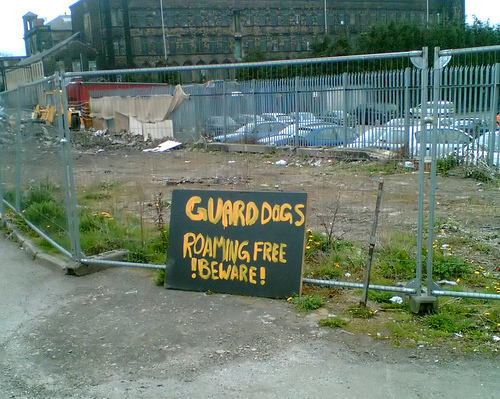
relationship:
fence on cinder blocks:
[2, 44, 500, 301] [409, 292, 439, 315]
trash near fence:
[388, 292, 403, 305] [2, 44, 500, 301]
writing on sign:
[182, 194, 304, 286] [162, 189, 309, 299]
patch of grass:
[82, 179, 117, 199] [2, 185, 170, 264]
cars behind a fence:
[204, 100, 499, 168] [87, 63, 499, 181]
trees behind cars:
[102, 6, 500, 113] [204, 100, 499, 168]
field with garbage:
[1, 106, 500, 354] [388, 292, 403, 305]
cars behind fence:
[204, 100, 499, 168] [2, 44, 500, 301]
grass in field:
[2, 185, 170, 264] [1, 106, 500, 354]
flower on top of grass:
[28, 177, 36, 194] [2, 185, 170, 264]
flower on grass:
[28, 177, 36, 194] [2, 185, 170, 264]